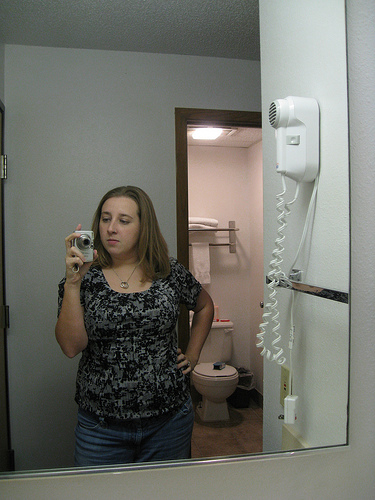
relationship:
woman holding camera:
[82, 187, 148, 273] [56, 223, 104, 288]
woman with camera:
[82, 187, 148, 273] [56, 223, 104, 288]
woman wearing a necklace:
[82, 187, 148, 273] [109, 268, 141, 298]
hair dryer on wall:
[246, 72, 330, 204] [257, 35, 334, 89]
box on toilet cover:
[214, 358, 231, 371] [191, 361, 242, 379]